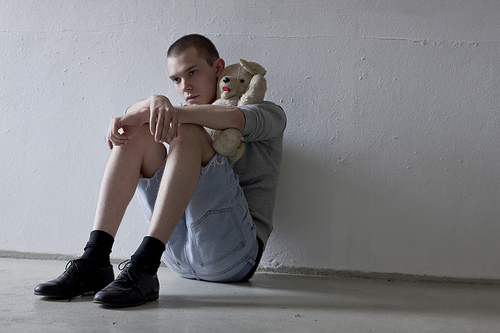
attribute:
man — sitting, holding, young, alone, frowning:
[92, 27, 345, 296]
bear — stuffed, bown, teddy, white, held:
[218, 55, 264, 135]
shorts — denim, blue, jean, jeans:
[178, 176, 241, 255]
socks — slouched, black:
[59, 220, 297, 284]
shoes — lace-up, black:
[47, 260, 133, 307]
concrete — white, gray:
[223, 291, 430, 314]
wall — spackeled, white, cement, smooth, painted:
[335, 14, 496, 157]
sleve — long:
[240, 106, 280, 139]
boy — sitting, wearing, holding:
[140, 40, 320, 164]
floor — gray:
[277, 288, 385, 321]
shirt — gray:
[237, 101, 274, 241]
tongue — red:
[220, 85, 234, 102]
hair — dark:
[148, 27, 222, 65]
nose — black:
[213, 71, 233, 90]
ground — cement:
[52, 300, 167, 332]